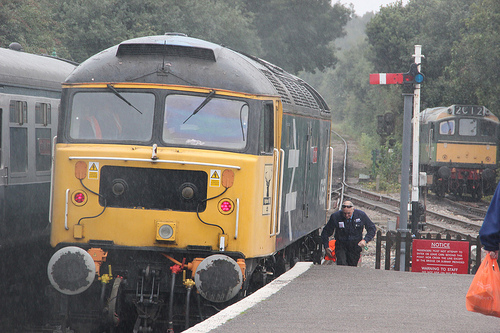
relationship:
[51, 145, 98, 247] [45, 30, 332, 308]
edge of train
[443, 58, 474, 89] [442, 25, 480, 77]
part of bush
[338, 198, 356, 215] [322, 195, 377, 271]
head of man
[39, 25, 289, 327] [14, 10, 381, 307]
front of train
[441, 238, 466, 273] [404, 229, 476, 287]
part of notice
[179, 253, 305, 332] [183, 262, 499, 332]
edge of platform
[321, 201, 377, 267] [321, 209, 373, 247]
man in jacket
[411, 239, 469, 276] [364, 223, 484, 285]
notice on fence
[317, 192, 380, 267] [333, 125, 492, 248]
man on tracks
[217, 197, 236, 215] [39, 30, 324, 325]
led light on right of train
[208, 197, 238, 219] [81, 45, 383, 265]
led light on train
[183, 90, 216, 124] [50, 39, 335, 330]
windshiel wiper on train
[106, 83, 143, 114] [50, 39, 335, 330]
windshiel wiper on train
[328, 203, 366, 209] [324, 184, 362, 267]
sunglasses on man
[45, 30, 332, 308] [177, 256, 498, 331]
train on platform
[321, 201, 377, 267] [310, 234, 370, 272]
man walking up stairs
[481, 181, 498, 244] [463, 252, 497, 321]
person holding bag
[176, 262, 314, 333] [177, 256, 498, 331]
line on platform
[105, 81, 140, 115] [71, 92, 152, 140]
windshiel wiper over window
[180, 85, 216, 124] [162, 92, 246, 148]
windshiel wiper over window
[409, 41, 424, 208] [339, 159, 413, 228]
post near tracks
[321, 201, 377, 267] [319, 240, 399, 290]
man walking up stairs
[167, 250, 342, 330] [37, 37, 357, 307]
line near train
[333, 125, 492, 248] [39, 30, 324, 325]
tracks behind train